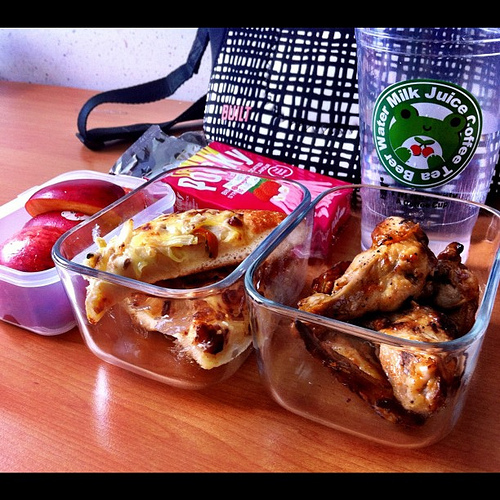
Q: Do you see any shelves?
A: No, there are no shelves.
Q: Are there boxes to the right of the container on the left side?
A: Yes, there is a box to the right of the container.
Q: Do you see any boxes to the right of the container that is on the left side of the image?
A: Yes, there is a box to the right of the container.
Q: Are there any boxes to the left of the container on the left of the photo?
A: No, the box is to the right of the container.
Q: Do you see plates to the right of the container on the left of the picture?
A: No, there is a box to the right of the container.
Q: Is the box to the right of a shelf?
A: No, the box is to the right of a container.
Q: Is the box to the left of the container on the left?
A: No, the box is to the right of the container.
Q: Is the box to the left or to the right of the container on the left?
A: The box is to the right of the container.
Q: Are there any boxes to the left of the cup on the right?
A: Yes, there is a box to the left of the cup.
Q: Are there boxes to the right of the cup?
A: No, the box is to the left of the cup.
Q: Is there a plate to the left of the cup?
A: No, there is a box to the left of the cup.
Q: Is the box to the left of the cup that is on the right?
A: Yes, the box is to the left of the cup.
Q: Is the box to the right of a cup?
A: No, the box is to the left of a cup.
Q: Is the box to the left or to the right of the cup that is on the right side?
A: The box is to the left of the cup.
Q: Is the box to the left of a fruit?
A: Yes, the box is to the left of a fruit.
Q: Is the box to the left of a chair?
A: No, the box is to the left of a fruit.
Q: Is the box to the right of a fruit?
A: No, the box is to the left of a fruit.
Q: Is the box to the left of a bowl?
A: No, the box is to the left of a fruit.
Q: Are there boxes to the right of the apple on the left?
A: Yes, there is a box to the right of the apple.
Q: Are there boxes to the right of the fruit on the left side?
A: Yes, there is a box to the right of the apple.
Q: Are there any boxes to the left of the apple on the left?
A: No, the box is to the right of the apple.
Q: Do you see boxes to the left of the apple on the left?
A: No, the box is to the right of the apple.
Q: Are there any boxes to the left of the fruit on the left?
A: No, the box is to the right of the apple.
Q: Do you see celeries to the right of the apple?
A: No, there is a box to the right of the apple.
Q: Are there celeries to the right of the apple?
A: No, there is a box to the right of the apple.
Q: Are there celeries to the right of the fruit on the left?
A: No, there is a box to the right of the apple.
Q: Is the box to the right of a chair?
A: No, the box is to the right of the apple.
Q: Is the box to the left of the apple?
A: No, the box is to the right of the apple.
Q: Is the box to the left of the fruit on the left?
A: No, the box is to the right of the apple.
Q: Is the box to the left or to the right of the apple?
A: The box is to the right of the apple.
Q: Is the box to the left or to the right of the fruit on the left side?
A: The box is to the right of the apple.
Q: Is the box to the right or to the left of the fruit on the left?
A: The box is to the right of the apple.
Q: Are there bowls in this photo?
A: No, there are no bowls.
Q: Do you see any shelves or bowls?
A: No, there are no bowls or shelves.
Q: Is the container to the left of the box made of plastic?
A: Yes, the container is made of plastic.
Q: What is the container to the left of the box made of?
A: The container is made of plastic.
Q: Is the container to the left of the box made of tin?
A: No, the container is made of plastic.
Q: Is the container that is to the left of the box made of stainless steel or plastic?
A: The container is made of plastic.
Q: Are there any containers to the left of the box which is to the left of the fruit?
A: Yes, there is a container to the left of the box.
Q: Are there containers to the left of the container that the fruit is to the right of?
A: Yes, there is a container to the left of the box.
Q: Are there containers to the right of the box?
A: No, the container is to the left of the box.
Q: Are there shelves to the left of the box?
A: No, there is a container to the left of the box.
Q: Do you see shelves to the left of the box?
A: No, there is a container to the left of the box.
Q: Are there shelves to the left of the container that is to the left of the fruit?
A: No, there is a container to the left of the box.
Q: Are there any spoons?
A: No, there are no spoons.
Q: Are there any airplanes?
A: No, there are no airplanes.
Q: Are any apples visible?
A: Yes, there is an apple.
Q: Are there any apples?
A: Yes, there is an apple.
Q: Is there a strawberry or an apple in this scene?
A: Yes, there is an apple.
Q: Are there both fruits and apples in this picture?
A: Yes, there are both an apple and a fruit.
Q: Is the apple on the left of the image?
A: Yes, the apple is on the left of the image.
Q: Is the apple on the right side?
A: No, the apple is on the left of the image.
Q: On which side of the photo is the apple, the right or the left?
A: The apple is on the left of the image.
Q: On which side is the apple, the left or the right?
A: The apple is on the left of the image.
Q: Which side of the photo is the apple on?
A: The apple is on the left of the image.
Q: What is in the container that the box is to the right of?
A: The apple is in the container.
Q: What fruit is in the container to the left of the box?
A: The fruit is an apple.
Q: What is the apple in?
A: The apple is in the container.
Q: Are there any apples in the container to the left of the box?
A: Yes, there is an apple in the container.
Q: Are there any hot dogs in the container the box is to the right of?
A: No, there is an apple in the container.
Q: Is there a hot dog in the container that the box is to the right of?
A: No, there is an apple in the container.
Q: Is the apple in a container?
A: Yes, the apple is in a container.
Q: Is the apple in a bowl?
A: No, the apple is in a container.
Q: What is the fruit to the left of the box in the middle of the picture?
A: The fruit is an apple.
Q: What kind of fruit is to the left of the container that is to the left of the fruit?
A: The fruit is an apple.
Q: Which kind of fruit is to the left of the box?
A: The fruit is an apple.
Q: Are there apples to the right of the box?
A: No, the apple is to the left of the box.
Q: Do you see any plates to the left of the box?
A: No, there is an apple to the left of the box.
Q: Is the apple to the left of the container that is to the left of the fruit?
A: Yes, the apple is to the left of the box.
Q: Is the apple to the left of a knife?
A: No, the apple is to the left of the box.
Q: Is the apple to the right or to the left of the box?
A: The apple is to the left of the box.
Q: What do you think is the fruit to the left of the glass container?
A: The fruit is an apple.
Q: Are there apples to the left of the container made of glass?
A: Yes, there is an apple to the left of the container.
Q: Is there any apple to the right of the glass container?
A: No, the apple is to the left of the container.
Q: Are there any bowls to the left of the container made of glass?
A: No, there is an apple to the left of the container.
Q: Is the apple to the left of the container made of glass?
A: Yes, the apple is to the left of the container.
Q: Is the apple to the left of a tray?
A: No, the apple is to the left of the container.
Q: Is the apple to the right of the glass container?
A: No, the apple is to the left of the container.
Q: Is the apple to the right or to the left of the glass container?
A: The apple is to the left of the container.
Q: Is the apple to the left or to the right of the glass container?
A: The apple is to the left of the container.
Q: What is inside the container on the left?
A: The apple is inside the container.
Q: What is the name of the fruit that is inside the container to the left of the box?
A: The fruit is an apple.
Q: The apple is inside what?
A: The apple is inside the container.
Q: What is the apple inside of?
A: The apple is inside the container.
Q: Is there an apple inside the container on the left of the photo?
A: Yes, there is an apple inside the container.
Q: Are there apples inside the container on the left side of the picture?
A: Yes, there is an apple inside the container.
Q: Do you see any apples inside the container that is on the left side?
A: Yes, there is an apple inside the container.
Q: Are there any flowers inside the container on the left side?
A: No, there is an apple inside the container.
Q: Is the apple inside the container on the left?
A: Yes, the apple is inside the container.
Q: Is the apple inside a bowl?
A: No, the apple is inside the container.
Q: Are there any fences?
A: No, there are no fences.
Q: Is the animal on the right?
A: Yes, the animal is on the right of the image.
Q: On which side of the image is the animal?
A: The animal is on the right of the image.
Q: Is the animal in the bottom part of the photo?
A: No, the animal is in the top of the image.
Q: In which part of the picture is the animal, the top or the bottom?
A: The animal is in the top of the image.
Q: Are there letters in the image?
A: Yes, there are letters.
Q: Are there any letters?
A: Yes, there are letters.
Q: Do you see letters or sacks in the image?
A: Yes, there are letters.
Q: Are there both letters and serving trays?
A: No, there are letters but no serving trays.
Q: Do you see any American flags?
A: No, there are no American flags.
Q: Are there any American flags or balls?
A: No, there are no American flags or balls.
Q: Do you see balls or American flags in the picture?
A: No, there are no American flags or balls.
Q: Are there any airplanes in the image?
A: No, there are no airplanes.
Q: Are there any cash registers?
A: No, there are no cash registers.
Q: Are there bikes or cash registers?
A: No, there are no cash registers or bikes.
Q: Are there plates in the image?
A: No, there are no plates.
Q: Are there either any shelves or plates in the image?
A: No, there are no plates or shelves.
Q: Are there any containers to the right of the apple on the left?
A: Yes, there is a container to the right of the apple.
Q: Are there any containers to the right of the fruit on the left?
A: Yes, there is a container to the right of the apple.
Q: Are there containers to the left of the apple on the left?
A: No, the container is to the right of the apple.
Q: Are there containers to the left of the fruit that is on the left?
A: No, the container is to the right of the apple.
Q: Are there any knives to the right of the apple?
A: No, there is a container to the right of the apple.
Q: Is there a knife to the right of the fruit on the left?
A: No, there is a container to the right of the apple.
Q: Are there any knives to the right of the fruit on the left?
A: No, there is a container to the right of the apple.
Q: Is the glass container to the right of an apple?
A: Yes, the container is to the right of an apple.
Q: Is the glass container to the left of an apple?
A: No, the container is to the right of an apple.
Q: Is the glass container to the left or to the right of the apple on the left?
A: The container is to the right of the apple.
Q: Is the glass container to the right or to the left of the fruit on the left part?
A: The container is to the right of the apple.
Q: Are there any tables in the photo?
A: Yes, there is a table.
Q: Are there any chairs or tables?
A: Yes, there is a table.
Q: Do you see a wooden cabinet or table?
A: Yes, there is a wood table.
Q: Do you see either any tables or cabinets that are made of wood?
A: Yes, the table is made of wood.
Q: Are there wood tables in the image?
A: Yes, there is a wood table.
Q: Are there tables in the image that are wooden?
A: Yes, there is a table that is wooden.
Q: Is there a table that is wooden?
A: Yes, there is a table that is wooden.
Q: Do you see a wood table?
A: Yes, there is a table that is made of wood.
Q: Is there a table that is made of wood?
A: Yes, there is a table that is made of wood.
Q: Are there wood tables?
A: Yes, there is a table that is made of wood.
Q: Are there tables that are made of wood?
A: Yes, there is a table that is made of wood.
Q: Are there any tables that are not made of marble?
A: Yes, there is a table that is made of wood.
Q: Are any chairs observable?
A: No, there are no chairs.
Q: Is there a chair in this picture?
A: No, there are no chairs.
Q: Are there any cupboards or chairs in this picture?
A: No, there are no chairs or cupboards.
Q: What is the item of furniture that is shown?
A: The piece of furniture is a table.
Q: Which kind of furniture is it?
A: The piece of furniture is a table.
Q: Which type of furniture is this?
A: This is a table.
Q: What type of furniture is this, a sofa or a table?
A: This is a table.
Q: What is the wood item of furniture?
A: The piece of furniture is a table.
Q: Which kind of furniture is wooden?
A: The furniture is a table.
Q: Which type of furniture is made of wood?
A: The furniture is a table.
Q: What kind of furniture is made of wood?
A: The furniture is a table.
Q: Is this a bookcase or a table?
A: This is a table.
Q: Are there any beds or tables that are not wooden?
A: No, there is a table but it is wooden.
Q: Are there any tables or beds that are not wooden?
A: No, there is a table but it is wooden.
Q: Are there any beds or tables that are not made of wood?
A: No, there is a table but it is made of wood.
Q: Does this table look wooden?
A: Yes, the table is wooden.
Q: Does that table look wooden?
A: Yes, the table is wooden.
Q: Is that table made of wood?
A: Yes, the table is made of wood.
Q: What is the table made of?
A: The table is made of wood.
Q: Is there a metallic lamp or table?
A: No, there is a table but it is wooden.